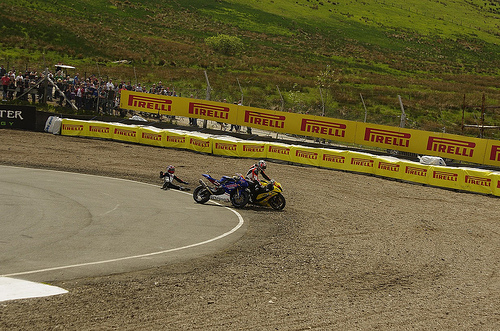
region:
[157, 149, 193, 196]
a man sitting on the ground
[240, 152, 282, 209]
a man on a motorcycle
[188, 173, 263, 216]
two motorcycles that collided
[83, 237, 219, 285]
a white line on a race track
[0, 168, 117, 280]
a paved race track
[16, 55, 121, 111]
several people in the stands at a race track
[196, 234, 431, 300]
dirt next to a race track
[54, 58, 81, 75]
a white umbrella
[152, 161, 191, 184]
a man with his arms stretched out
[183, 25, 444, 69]
a hillside with grass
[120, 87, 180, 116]
red pirelli sign on wall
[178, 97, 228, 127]
red pirelli sign on wall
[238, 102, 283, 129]
red pirelli sign on wall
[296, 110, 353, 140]
red pirelli sign on wall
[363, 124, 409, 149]
red pirelli sign on wall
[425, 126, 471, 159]
red pirelli sign on wall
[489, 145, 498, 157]
red pirelli sign on wall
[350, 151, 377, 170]
red pirelli sign on wall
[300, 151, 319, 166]
red pirelli sign on wall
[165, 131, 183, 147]
red pirelli sign on wall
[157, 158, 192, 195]
man fallen on ground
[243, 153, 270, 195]
man riding motorcyle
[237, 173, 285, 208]
yellow sport motorcycle on ground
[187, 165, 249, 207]
blue and red motorcycle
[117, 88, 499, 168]
Red and yellow Pirelli advertisement boards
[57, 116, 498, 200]
hay bales covered in plastic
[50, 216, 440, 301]
bike tracks in dirt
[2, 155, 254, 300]
side of race track turn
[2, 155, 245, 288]
white paint stripe on edge of track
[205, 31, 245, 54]
large bush on hillside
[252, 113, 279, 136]
red pirelli sign on wall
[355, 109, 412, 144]
red pirelli sign on wall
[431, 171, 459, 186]
red pirelli sign on wall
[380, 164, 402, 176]
red pirelli sign on wall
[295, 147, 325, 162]
red pirelli sign on wall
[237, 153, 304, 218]
yellow motor bike on the dirt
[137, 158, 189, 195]
rider on the ground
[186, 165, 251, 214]
blue motor bike on the track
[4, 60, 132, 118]
fans in the audience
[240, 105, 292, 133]
pirelli banner on the side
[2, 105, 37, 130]
black banner in front of the people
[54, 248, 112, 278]
white line on the road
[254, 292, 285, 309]
rocks in the dirt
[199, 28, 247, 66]
green bus in the background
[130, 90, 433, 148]
red and yellow banner